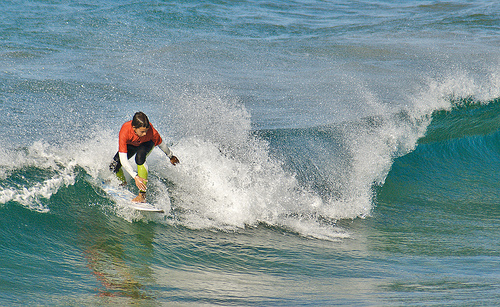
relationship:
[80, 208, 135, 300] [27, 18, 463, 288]
reflection in the water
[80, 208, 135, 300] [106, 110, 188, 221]
reflection of a surfer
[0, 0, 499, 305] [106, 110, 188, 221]
water in surfer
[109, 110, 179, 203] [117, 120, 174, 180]
boy wearing shirt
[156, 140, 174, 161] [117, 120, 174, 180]
sleeve on shirt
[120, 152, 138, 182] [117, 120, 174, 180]
sleeve on shirt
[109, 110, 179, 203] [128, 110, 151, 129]
boy has boy hair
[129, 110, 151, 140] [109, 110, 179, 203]
head of boy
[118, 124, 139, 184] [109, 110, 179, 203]
arm of boy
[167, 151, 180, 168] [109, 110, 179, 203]
hand of boy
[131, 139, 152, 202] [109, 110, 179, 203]
leg of boy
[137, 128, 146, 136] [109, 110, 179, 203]
eye of boy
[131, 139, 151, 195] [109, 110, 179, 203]
leg of boy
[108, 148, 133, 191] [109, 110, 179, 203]
leg of boy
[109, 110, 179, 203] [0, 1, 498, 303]
boy surfing in water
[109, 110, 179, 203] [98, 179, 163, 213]
boy on surfboard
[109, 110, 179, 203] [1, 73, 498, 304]
boy riding wave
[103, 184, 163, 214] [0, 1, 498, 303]
surfboard in water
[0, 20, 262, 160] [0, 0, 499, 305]
water splashing in water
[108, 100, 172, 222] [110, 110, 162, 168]
boy wearing dress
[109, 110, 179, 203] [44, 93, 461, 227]
boy surfing wave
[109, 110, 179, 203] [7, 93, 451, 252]
boy surfing wave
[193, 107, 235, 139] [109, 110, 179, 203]
droplet by boy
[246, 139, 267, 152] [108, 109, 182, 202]
water droplet by surfer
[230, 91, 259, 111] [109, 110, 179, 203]
water droplet by boy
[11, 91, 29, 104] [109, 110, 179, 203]
water droplet by boy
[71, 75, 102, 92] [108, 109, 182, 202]
water droplet by surfer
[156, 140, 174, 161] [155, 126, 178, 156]
sleeve on arm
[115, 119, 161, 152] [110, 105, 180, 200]
shirt on surfer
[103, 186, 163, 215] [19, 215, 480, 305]
surfboard in water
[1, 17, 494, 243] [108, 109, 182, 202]
wave behind surfer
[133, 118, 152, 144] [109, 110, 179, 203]
face on boy